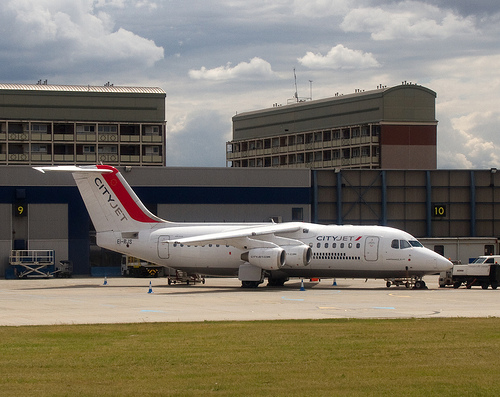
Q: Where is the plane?
A: At an airport.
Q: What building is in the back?
A: An airport.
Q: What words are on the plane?
A: CityJet.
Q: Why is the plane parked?
A: For fueling.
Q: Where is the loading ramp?
A: By the building.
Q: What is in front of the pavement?
A: Grass.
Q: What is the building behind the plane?
A: Airport.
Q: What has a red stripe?
A: Plane.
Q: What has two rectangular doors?
A: Plane.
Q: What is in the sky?
A: Clouds.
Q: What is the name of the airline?
A: City Jet.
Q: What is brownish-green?
A: Grass.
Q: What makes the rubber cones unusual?
A: They are blue.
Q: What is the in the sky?
A: Clouds.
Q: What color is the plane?
A: White.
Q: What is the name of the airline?
A: Cityjet.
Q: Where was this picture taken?
A: An airport.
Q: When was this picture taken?
A: During the day.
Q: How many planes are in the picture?
A: One.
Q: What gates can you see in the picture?
A: Nine and ten.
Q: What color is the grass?
A: Green.